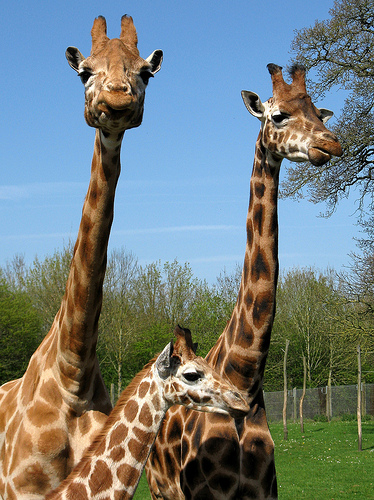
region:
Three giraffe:
[5, 5, 356, 487]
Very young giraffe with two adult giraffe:
[31, 318, 259, 498]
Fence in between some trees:
[278, 376, 373, 424]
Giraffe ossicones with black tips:
[260, 53, 315, 96]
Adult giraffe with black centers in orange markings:
[161, 54, 352, 498]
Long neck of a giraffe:
[51, 115, 147, 367]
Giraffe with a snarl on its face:
[56, 9, 189, 154]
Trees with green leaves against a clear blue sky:
[286, 20, 365, 413]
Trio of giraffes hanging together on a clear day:
[5, 3, 352, 494]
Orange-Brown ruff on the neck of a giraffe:
[38, 360, 152, 497]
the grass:
[290, 411, 338, 498]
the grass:
[316, 419, 343, 487]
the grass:
[292, 444, 319, 496]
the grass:
[305, 422, 343, 462]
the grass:
[309, 439, 349, 492]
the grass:
[319, 395, 351, 493]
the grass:
[309, 460, 323, 497]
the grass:
[329, 454, 352, 496]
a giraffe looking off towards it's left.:
[145, 319, 271, 439]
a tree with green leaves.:
[92, 249, 174, 403]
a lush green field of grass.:
[265, 420, 372, 498]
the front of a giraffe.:
[173, 412, 281, 499]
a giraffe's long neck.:
[218, 159, 289, 341]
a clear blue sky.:
[0, 0, 371, 309]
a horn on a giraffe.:
[291, 51, 318, 99]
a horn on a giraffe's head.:
[117, 5, 153, 48]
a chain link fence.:
[263, 380, 371, 424]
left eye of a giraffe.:
[129, 54, 160, 93]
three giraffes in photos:
[5, 21, 347, 498]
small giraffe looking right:
[100, 326, 233, 498]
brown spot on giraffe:
[122, 441, 148, 462]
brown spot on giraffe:
[114, 466, 135, 488]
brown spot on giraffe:
[107, 446, 124, 460]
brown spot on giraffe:
[94, 466, 115, 490]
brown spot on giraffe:
[123, 398, 135, 420]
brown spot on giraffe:
[141, 406, 152, 426]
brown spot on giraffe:
[25, 403, 54, 423]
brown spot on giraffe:
[64, 482, 85, 497]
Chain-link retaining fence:
[304, 385, 357, 424]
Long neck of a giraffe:
[239, 178, 281, 342]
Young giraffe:
[126, 320, 256, 428]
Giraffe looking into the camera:
[63, 11, 170, 139]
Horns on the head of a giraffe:
[259, 57, 316, 98]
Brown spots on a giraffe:
[18, 394, 83, 463]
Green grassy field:
[277, 433, 354, 498]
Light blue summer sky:
[178, 23, 262, 83]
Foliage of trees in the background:
[5, 305, 26, 359]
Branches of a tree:
[315, 6, 371, 90]